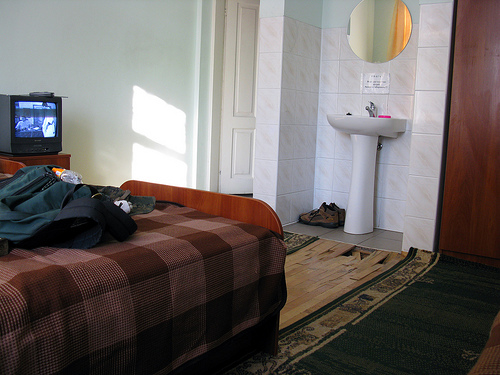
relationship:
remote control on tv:
[30, 92, 55, 98] [0, 95, 64, 157]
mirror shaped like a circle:
[346, 0, 413, 65] [347, 1, 413, 65]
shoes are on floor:
[297, 203, 346, 229] [225, 209, 500, 375]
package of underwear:
[51, 166, 84, 184] [51, 166, 84, 186]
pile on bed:
[0, 165, 159, 254] [0, 179, 288, 374]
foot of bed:
[0, 160, 27, 175] [1, 157, 27, 181]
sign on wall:
[360, 70, 391, 95] [312, 25, 420, 233]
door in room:
[216, 0, 261, 199] [0, 0, 499, 375]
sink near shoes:
[327, 103, 407, 235] [297, 203, 346, 229]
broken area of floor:
[299, 238, 402, 284] [225, 209, 500, 375]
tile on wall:
[252, 3, 453, 255] [312, 25, 420, 233]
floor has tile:
[283, 209, 404, 252] [252, 3, 453, 255]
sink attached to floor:
[327, 103, 407, 235] [283, 209, 404, 252]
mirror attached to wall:
[346, 0, 413, 65] [313, 0, 421, 246]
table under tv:
[2, 153, 72, 170] [0, 95, 64, 157]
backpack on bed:
[1, 165, 137, 254] [0, 179, 288, 374]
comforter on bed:
[0, 201, 289, 373] [0, 179, 288, 374]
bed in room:
[0, 179, 288, 374] [0, 0, 499, 375]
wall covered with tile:
[252, 0, 454, 251] [252, 3, 453, 255]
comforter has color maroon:
[0, 201, 289, 373] [0, 201, 288, 374]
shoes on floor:
[297, 203, 346, 229] [283, 209, 404, 252]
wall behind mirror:
[313, 0, 421, 246] [346, 0, 413, 65]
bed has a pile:
[0, 179, 288, 374] [0, 165, 159, 254]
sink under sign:
[327, 103, 407, 235] [360, 70, 391, 95]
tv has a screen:
[0, 95, 64, 157] [15, 101, 59, 139]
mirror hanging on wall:
[346, 0, 413, 65] [313, 0, 421, 246]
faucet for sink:
[364, 100, 377, 118] [327, 103, 407, 235]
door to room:
[216, 0, 261, 199] [0, 0, 499, 375]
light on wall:
[97, 85, 191, 192] [0, 0, 209, 191]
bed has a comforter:
[0, 179, 288, 374] [0, 201, 289, 373]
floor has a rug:
[225, 209, 500, 375] [203, 230, 499, 373]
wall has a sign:
[312, 25, 420, 233] [360, 70, 391, 95]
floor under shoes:
[283, 209, 404, 252] [297, 203, 346, 229]